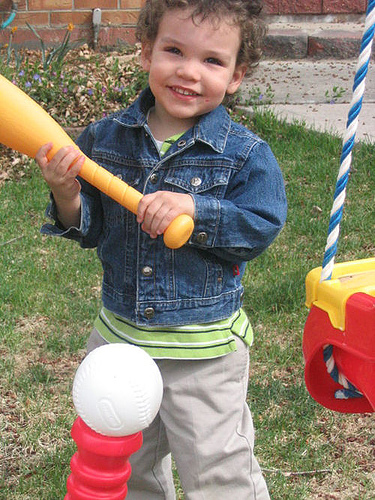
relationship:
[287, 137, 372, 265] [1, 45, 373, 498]
grass covering ground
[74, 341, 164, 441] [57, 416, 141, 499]
ball on toy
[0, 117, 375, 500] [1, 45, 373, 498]
grass on ground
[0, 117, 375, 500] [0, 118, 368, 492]
grass on ground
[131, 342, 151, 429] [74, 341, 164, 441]
design on ball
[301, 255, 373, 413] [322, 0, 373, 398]
swing on rope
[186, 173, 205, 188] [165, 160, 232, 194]
button on pocket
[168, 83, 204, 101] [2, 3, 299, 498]
teeth on child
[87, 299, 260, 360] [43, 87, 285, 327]
shirt on jacket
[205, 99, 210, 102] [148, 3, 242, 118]
mark on face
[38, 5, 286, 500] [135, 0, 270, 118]
boy looks happy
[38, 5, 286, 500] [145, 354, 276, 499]
boy wearing pants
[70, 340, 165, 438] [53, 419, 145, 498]
ball on tee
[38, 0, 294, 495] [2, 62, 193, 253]
boy holding bat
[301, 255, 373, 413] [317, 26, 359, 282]
swing on rope